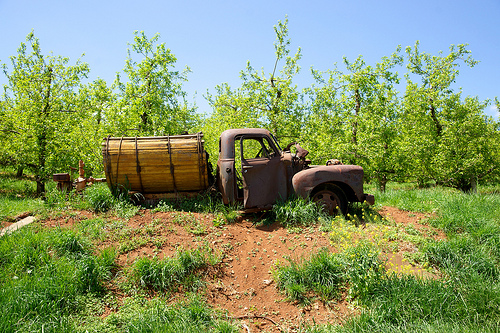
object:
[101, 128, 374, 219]
abandoned truck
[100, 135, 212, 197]
wooden slats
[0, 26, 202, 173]
fruit orchard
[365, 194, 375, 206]
bumper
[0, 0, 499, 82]
blue sky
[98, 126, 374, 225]
pickup truck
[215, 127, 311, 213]
cab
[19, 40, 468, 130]
orchard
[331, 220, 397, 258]
flowers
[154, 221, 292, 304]
dirt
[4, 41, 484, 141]
trees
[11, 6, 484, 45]
sky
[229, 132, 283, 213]
door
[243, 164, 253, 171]
handle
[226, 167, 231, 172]
cap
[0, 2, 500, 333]
field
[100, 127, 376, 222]
car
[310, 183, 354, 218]
wheel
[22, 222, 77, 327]
grass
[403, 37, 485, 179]
tree